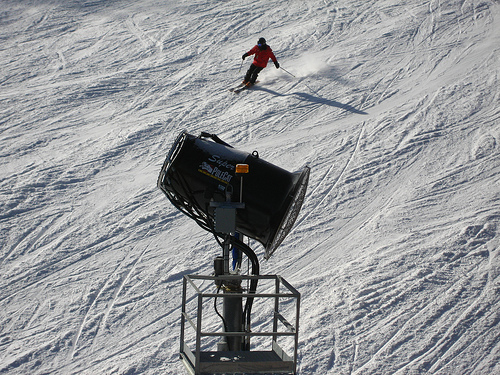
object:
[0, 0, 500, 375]
ground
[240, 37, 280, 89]
man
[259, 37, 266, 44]
helmet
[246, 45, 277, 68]
jacket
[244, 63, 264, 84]
pants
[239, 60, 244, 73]
poles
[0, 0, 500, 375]
mountain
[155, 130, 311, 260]
light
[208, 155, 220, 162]
letters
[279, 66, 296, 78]
pole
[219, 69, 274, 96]
skiing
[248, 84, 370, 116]
shadow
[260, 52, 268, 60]
red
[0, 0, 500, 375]
snow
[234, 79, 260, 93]
skis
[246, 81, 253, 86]
feet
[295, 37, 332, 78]
snow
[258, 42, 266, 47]
mask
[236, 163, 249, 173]
light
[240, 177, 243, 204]
pole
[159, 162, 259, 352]
wires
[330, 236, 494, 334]
lines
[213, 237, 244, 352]
mast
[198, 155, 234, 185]
brand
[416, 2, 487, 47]
imprints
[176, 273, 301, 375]
frame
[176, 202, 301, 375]
stand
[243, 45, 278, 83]
snowsuit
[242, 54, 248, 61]
gloves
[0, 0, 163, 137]
heap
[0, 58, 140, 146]
ice